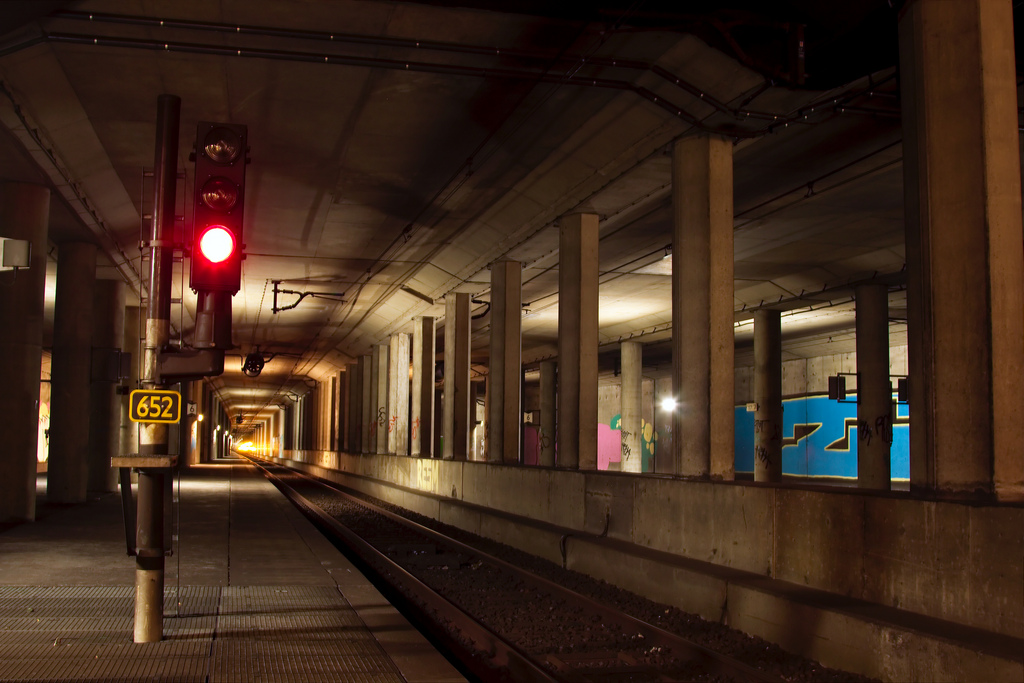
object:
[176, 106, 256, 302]
traffic light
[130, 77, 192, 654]
pole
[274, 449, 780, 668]
rail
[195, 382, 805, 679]
train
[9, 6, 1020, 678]
train station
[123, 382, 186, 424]
sign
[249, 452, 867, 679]
dirt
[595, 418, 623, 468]
paint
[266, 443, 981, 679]
barrier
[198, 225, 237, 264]
light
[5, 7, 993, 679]
tunnel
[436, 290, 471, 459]
support column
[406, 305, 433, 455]
support column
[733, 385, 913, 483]
art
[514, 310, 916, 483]
wall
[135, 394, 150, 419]
number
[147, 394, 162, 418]
number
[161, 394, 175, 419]
number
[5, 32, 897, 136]
conduit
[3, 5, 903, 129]
conduit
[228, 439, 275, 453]
light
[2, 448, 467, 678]
platform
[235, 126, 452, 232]
shadow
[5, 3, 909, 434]
ceiling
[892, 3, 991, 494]
pole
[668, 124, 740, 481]
pole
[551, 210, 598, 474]
pole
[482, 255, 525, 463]
pole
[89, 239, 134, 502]
pole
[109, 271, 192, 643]
pole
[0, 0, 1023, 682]
building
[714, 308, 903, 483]
building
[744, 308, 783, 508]
pole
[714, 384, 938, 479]
graffiti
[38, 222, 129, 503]
plinth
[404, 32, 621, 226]
electrical wires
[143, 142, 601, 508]
protective coating